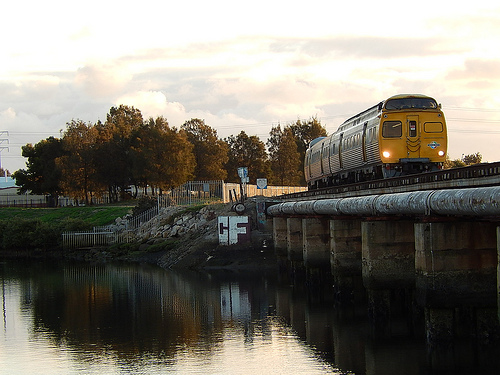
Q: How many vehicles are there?
A: One.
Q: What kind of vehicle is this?
A: A train.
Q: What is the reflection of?
A: Trees.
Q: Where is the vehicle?
A: On the bridge.